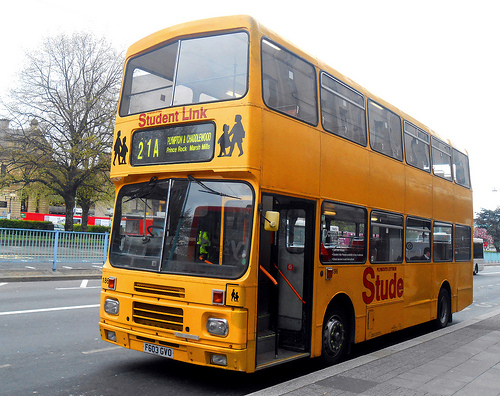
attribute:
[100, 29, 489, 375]
bus — yellow, double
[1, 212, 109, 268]
fence — blue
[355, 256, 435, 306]
writing — red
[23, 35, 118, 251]
tree — leafless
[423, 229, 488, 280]
bus — white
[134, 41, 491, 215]
floor — top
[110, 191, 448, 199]
floor — bottom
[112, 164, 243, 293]
window — windshield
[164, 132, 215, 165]
lettering — yellow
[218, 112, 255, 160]
man — printed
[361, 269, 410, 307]
print — red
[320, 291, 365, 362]
wheel — black